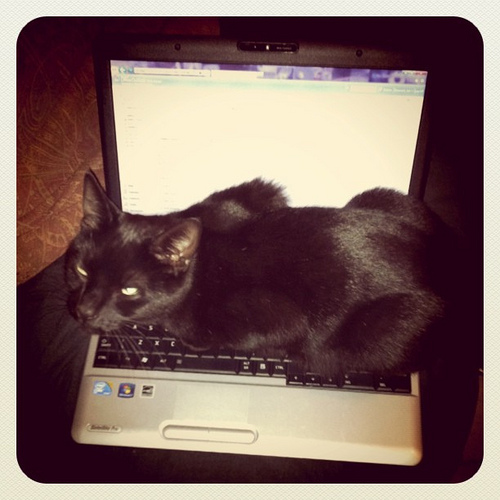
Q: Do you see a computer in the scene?
A: Yes, there is a computer.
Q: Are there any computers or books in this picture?
A: Yes, there is a computer.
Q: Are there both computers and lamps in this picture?
A: No, there is a computer but no lamps.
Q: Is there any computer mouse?
A: No, there are no computer mice.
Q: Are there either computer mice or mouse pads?
A: No, there are no computer mice or mouse pads.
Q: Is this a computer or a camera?
A: This is a computer.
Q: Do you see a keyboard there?
A: Yes, there is a keyboard.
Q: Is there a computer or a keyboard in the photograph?
A: Yes, there is a keyboard.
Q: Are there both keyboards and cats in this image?
A: Yes, there are both a keyboard and a cat.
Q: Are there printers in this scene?
A: No, there are no printers.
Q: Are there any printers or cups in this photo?
A: No, there are no printers or cups.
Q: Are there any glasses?
A: No, there are no glasses.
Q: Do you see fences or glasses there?
A: No, there are no glasses or fences.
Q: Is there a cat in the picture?
A: Yes, there is a cat.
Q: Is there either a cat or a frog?
A: Yes, there is a cat.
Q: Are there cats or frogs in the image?
A: Yes, there is a cat.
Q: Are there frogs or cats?
A: Yes, there is a cat.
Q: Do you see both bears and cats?
A: No, there is a cat but no bears.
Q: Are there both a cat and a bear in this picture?
A: No, there is a cat but no bears.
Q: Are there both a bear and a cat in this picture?
A: No, there is a cat but no bears.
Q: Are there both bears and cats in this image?
A: No, there is a cat but no bears.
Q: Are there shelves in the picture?
A: No, there are no shelves.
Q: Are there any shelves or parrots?
A: No, there are no shelves or parrots.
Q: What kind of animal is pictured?
A: The animal is a cat.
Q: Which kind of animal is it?
A: The animal is a cat.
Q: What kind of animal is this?
A: This is a cat.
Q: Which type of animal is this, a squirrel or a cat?
A: This is a cat.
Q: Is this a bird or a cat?
A: This is a cat.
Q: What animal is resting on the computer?
A: The animal is a cat.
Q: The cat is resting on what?
A: The cat is resting on the computer.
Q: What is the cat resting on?
A: The cat is resting on the computer.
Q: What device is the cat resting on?
A: The cat is resting on the computer.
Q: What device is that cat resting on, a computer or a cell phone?
A: The cat is resting on a computer.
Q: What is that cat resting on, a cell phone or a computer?
A: The cat is resting on a computer.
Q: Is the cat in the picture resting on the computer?
A: Yes, the cat is resting on the computer.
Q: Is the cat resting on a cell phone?
A: No, the cat is resting on the computer.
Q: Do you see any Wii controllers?
A: No, there are no Wii controllers.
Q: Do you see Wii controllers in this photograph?
A: No, there are no Wii controllers.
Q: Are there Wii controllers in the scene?
A: No, there are no Wii controllers.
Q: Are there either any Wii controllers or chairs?
A: No, there are no Wii controllers or chairs.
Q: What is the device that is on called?
A: The device is a screen.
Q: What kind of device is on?
A: The device is a screen.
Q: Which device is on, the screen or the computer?
A: The screen is on.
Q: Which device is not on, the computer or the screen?
A: The computer is not on.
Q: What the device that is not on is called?
A: The device is a computer.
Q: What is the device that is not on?
A: The device is a computer.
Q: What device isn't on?
A: The device is a computer.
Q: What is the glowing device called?
A: The device is a screen.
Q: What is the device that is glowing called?
A: The device is a screen.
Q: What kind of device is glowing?
A: The device is a screen.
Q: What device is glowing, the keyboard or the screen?
A: The screen is glowing.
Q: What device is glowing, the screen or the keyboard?
A: The screen is glowing.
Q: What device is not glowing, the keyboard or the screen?
A: The keyboard is not glowing.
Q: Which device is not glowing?
A: The device is a keyboard.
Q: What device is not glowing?
A: The device is a keyboard.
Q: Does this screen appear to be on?
A: Yes, the screen is on.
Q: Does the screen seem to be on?
A: Yes, the screen is on.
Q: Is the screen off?
A: No, the screen is on.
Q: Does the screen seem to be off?
A: No, the screen is on.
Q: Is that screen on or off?
A: The screen is on.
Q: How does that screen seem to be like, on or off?
A: The screen is on.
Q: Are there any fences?
A: No, there are no fences.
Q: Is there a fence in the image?
A: No, there are no fences.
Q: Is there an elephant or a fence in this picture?
A: No, there are no fences or elephants.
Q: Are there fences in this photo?
A: No, there are no fences.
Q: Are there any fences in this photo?
A: No, there are no fences.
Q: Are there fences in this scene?
A: No, there are no fences.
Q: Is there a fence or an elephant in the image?
A: No, there are no fences or elephants.